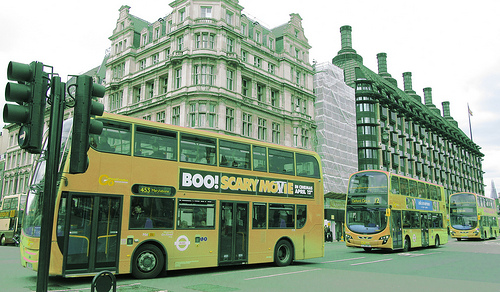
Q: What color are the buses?
A: Yellow.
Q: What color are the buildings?
A: Beige.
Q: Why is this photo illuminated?
A: Sunlight.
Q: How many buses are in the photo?
A: 3.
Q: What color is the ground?
A: Gray.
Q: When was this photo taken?
A: During the day.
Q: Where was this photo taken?
A: On a city street.